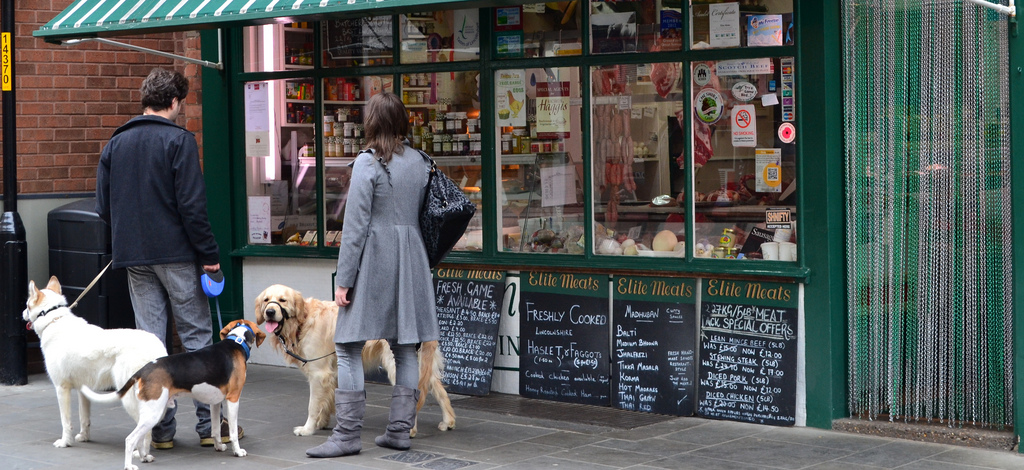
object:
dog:
[80, 319, 267, 470]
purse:
[417, 149, 477, 269]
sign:
[731, 104, 758, 147]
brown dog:
[255, 282, 458, 436]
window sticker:
[781, 58, 797, 123]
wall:
[13, 0, 200, 200]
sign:
[520, 271, 616, 407]